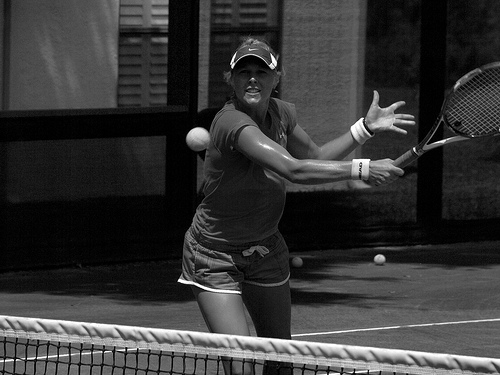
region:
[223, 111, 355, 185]
the arm of a woman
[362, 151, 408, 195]
the hand of a woman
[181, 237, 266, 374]
the leg of a woman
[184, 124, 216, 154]
a tennis ball in the air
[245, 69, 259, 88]
the nose of a woman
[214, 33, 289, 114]
the head of a woman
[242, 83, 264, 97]
the mouth of a woman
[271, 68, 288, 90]
the ear of a woman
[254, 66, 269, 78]
the eye of a woman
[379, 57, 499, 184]
a tennis racket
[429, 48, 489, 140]
A racket is visible.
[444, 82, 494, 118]
A racket is visible.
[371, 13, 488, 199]
A racket is visible.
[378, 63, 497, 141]
A racket is visible.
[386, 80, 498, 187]
A racket is visible.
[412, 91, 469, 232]
A racket is visible.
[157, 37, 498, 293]
a woman holding a tennis racket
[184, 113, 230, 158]
a tennis ball in the air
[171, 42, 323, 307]
a woman wearing shorts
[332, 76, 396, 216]
a woman wearing wrist bands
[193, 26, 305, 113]
a woman wearing a sun visor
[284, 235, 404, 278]
two tennis balls on the ground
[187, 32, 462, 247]
a woman with her hand out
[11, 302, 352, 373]
a tennis court net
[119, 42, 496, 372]
a woman playing tennis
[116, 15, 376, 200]
a woman looking at a tennis ball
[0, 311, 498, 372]
Tennis net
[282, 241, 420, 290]
two tennis balls on ground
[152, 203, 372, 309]
Short women's tennis shorts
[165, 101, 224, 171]
Tennis ball flyin mid-air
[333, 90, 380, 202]
Two absorbent sports wristsbands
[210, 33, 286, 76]
Nike tennis visor being worn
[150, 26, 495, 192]
Women playing tennis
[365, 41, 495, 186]
Tennis racket being held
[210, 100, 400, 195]
Sweat glistening on woman's arm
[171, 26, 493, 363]
Women playing intensely sports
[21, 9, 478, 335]
the picture is black and white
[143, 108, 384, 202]
the ball is in the air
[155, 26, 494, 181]
the woman is holding a tennis racket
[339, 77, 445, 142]
the woman`s hand is open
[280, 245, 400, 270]
the balls are on the floor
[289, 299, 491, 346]
the white line is on the floor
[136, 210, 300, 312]
the woman is wearing shorts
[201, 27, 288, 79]
woman wearing a visor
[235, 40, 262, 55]
the sign on the hat is nike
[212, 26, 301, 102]
the woman is smiling